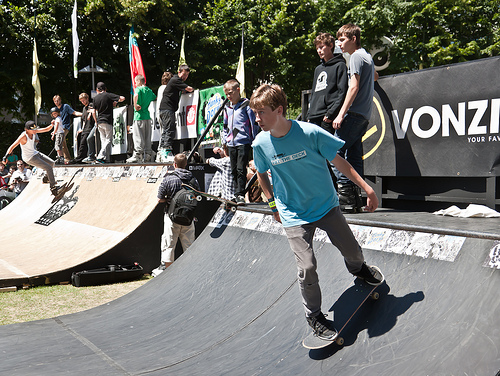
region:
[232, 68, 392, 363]
boy standing on a black skateboard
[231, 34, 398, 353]
boy wearing a turquoise shirt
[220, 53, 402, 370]
boy wearing khaki pants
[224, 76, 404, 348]
boy wearing black tennis shoes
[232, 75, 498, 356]
boys skateboarding on a skateboard ramp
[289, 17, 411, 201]
two boys watching skateboarders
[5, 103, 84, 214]
boy wearing a white tank shirt skateboarding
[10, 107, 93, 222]
boy wearing a black cap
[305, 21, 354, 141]
boy wearing a black pullover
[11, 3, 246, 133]
flags on poles behind a group of boys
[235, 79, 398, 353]
a boy on a skateboard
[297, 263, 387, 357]
a black and white skateboard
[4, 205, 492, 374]
a black skateboard half pipe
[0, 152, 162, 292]
a tan skateboard half pipe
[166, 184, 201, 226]
a black backpack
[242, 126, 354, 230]
a men's light blue t-shirt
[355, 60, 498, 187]
a promotional advertisement board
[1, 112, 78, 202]
a skateboarder in half pipe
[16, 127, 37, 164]
a men's white tank top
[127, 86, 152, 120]
men's green t-shirt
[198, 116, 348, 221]
boy wearing blue shirt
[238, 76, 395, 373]
the boy is skateboarding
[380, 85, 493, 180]
white letters on black wall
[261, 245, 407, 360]
the skateboard is black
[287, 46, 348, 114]
boy's sweater is black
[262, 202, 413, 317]
boy's pants are gray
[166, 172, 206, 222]
boy wearing a backpack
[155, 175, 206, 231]
the backpack is black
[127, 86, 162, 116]
boy's shirt is green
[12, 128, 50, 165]
man wearing a tank top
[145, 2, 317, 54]
The trees have leaves.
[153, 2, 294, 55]
The trees are green.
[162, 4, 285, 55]
Trees are in the background.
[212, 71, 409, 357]
The person is on a skateboard.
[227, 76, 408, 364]
The skateboard is black.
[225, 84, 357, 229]
The person is wearing a blue top.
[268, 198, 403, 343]
The person is wearing gray pants.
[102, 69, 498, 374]
The person is on a ramp.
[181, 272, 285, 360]
The ramp is black.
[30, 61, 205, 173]
People are standing.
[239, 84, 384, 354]
a young man on a skateboard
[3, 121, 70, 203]
a man on a skateboard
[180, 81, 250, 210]
a young boy waiting to drop in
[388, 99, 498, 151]
a white logo on a black tarp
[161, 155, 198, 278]
a young man wearing a backpack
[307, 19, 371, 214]
two boys on top of a quarter pipe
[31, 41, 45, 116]
a yellow flag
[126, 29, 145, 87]
an american flag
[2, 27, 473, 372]
young men on two quarter pipes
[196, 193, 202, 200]
white skateboard wheel